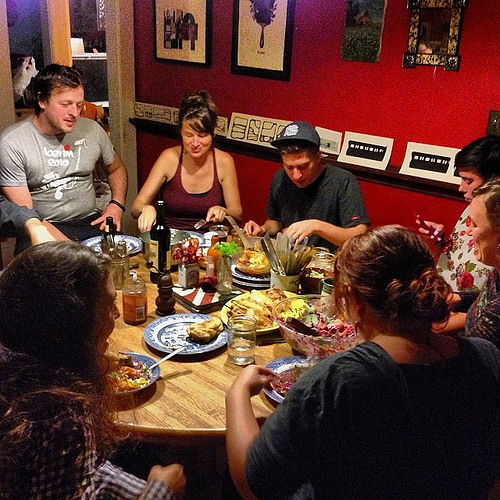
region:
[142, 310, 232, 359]
piece of food on white and blue plate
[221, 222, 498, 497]
woman eating food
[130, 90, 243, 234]
woman holding a fork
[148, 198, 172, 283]
dark glass wine bottle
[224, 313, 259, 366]
glass jar of water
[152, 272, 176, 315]
wood salt or pepper shaker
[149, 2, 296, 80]
framed pictures on wall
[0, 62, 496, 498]
people seated around table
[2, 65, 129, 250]
man in gray shirt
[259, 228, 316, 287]
cup of butter knives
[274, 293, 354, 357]
utensil in glass bowl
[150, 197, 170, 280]
label on bottle of wine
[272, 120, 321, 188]
hat on man's head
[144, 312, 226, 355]
blue and white plate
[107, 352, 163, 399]
plate full of food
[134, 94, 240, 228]
woman in tank top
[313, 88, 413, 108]
red paint on wall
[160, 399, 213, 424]
brown color on the table top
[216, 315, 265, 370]
small clear drinking glass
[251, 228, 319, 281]
silver ware in the cup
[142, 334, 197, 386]
utensil at end of plate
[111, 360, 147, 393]
food on blue plate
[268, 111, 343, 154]
black cap with logo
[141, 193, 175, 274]
tall bottle of wine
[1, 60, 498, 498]
people sitting around a table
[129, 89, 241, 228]
woman holding a fork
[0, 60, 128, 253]
man wearing a tight gray shirt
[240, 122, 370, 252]
man wearing a hat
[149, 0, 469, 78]
four pieces of artwork on red wall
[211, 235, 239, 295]
plant in small glass vase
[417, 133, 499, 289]
person looking at their cellphone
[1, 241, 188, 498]
person in a plaid shirt laughing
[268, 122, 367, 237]
The man is wearing a hat.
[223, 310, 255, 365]
A glass of water is on the table.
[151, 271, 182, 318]
The salt shaker is made of wood.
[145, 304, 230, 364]
The plates are blue and white.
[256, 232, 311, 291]
Silverware is in a cup.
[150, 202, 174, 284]
A bottle of wine is on the table.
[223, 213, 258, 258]
A wooden spoon is in the bowl.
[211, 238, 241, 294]
The center pieces have flowers.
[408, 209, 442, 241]
The phone is red and slim.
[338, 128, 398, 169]
Signs are along the wall.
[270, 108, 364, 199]
a man wearing a hat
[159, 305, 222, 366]
a plate on the table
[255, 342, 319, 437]
a plate on the table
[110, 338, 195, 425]
a plate on the table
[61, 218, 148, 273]
a plate on the table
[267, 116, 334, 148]
The man is wearing a black cap.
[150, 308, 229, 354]
The plate is blue and white.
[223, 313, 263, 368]
A glass of water on the table.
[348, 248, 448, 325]
The girl hair is in a ponytail.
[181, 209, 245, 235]
The woman is holding a fork in her hand.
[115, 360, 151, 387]
Food on top of the plate.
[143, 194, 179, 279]
A bottle of wine on the table.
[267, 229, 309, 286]
Utensils in the mug.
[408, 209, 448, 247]
The person is holding a cell phone in hand.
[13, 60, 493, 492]
People sitting around a table full of food.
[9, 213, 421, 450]
A round wooden table.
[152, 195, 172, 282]
A black tall bottle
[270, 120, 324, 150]
A ball cap.